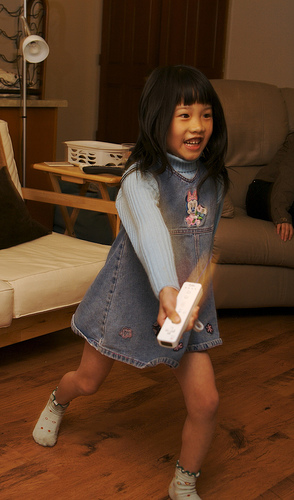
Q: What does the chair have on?
A: Cushions.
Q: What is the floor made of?
A: Wood.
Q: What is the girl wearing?
A: Jean dress.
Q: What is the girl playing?
A: Wii.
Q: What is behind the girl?
A: Chair.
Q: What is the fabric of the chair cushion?
A: Cloth.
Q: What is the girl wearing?
A: Blue denim dress.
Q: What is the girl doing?
A: Leaning forward.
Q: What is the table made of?
A: Wood.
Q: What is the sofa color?
A: Beige.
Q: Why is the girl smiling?
A: She's playing a game.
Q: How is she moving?
A: She's lunging forward.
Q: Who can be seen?
A: A young girl.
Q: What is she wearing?
A: A denim dress.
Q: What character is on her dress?
A: Minnie Mouse.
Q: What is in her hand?
A: A gaming controller.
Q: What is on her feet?
A: Socks.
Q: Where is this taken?
A: A living room.